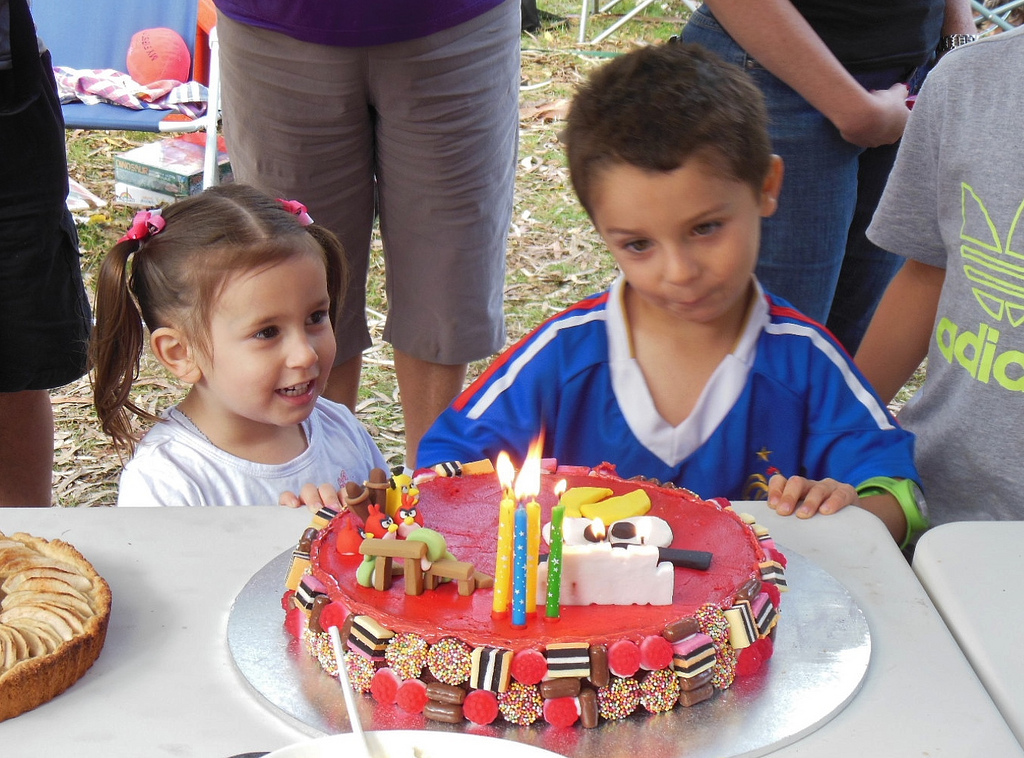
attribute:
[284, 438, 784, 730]
cake — red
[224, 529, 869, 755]
metal tray — silver, circular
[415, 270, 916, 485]
jersey — blue, soccer jersey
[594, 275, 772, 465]
collar — white 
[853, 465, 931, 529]
watch — lime green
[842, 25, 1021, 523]
gray shirt — short sleeve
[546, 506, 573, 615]
green candle — birthday cake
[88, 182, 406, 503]
girl — Little 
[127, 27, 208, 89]
balloon — Pink 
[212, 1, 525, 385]
capris — gray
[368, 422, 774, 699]
cake — birthday cake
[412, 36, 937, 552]
boy — little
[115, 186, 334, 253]
barettes — pink